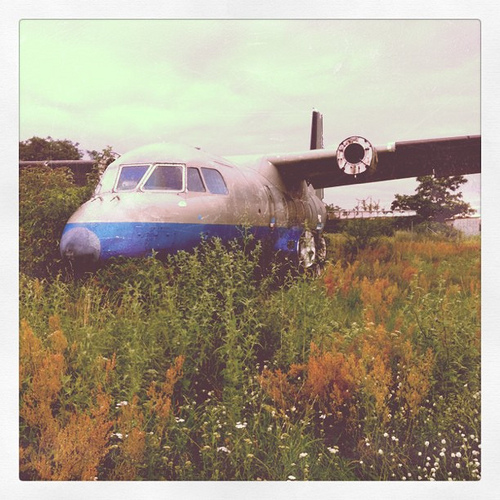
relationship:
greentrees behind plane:
[26, 127, 115, 272] [29, 91, 474, 302]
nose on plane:
[59, 227, 101, 269] [21, 43, 462, 308]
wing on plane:
[268, 134, 481, 190] [24, 107, 471, 266]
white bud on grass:
[327, 445, 339, 454] [23, 164, 490, 489]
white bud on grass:
[391, 435, 398, 442] [23, 164, 490, 489]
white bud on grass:
[298, 452, 308, 457] [23, 164, 490, 489]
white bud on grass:
[235, 422, 247, 429] [23, 164, 490, 489]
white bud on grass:
[175, 417, 184, 422] [23, 164, 490, 489]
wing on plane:
[268, 134, 481, 190] [13, 105, 485, 293]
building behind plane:
[331, 207, 478, 242] [24, 100, 481, 281]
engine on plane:
[335, 137, 380, 180] [24, 107, 471, 266]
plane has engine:
[24, 107, 471, 266] [333, 132, 375, 180]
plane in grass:
[24, 107, 471, 266] [18, 211, 478, 478]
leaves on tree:
[391, 176, 472, 218] [393, 174, 475, 229]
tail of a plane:
[303, 110, 334, 216] [24, 101, 492, 305]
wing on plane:
[271, 134, 481, 191] [18, 103, 479, 317]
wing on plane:
[268, 134, 481, 190] [24, 100, 481, 281]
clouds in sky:
[100, 48, 410, 107] [25, 28, 479, 168]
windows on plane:
[271, 190, 323, 219] [24, 107, 471, 266]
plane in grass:
[19, 110, 482, 268] [68, 250, 456, 389]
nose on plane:
[52, 217, 107, 282] [24, 107, 471, 266]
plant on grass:
[260, 316, 440, 443] [18, 211, 478, 478]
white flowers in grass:
[116, 371, 486, 482] [37, 237, 482, 477]